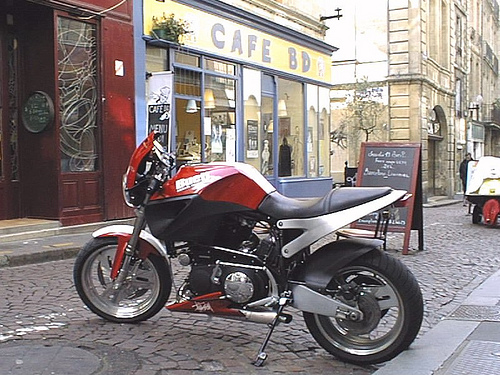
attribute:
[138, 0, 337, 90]
sign — yellow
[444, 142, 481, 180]
shirt — black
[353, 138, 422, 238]
sign — yellow, Blue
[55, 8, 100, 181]
glass — decorative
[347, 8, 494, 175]
building — yellow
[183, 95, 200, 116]
shade — white